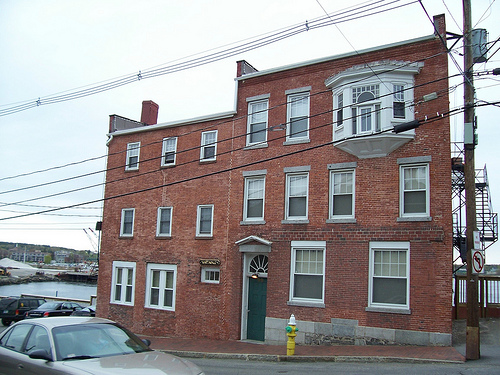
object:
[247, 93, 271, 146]
window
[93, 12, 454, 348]
building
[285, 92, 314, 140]
window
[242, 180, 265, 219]
window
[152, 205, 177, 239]
windows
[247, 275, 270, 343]
door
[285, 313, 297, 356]
fire hydrant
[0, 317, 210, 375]
car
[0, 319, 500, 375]
road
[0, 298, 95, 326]
row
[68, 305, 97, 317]
cars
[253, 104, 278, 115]
lines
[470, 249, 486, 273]
sign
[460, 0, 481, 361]
pole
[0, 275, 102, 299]
sea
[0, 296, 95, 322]
side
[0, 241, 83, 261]
buildings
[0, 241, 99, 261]
mountain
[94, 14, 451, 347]
wall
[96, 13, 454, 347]
house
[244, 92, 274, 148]
frame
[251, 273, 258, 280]
light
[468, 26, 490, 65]
transformer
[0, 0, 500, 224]
power lines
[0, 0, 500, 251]
sky